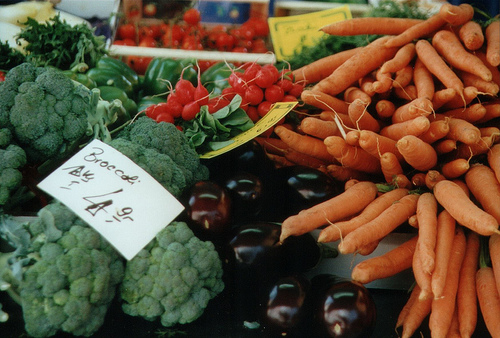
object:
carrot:
[430, 179, 500, 236]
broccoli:
[0, 60, 114, 154]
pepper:
[214, 33, 237, 54]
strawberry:
[117, 23, 138, 41]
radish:
[176, 63, 196, 104]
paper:
[36, 138, 187, 260]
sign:
[266, 5, 362, 61]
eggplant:
[176, 182, 239, 246]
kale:
[184, 89, 243, 149]